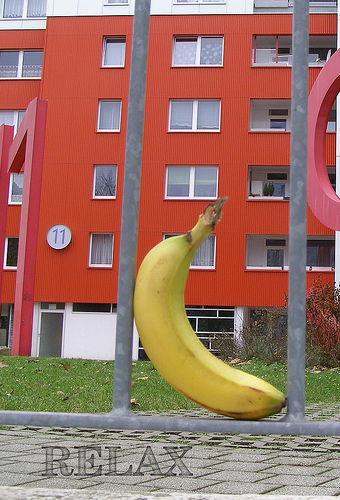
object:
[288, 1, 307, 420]
bar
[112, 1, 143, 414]
bar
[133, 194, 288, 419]
banana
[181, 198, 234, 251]
stem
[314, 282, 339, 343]
leaves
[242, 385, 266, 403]
bruisies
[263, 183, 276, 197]
bush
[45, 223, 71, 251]
circle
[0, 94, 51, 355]
sculpture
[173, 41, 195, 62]
curtain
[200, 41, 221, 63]
curtain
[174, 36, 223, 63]
window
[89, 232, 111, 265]
windows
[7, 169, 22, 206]
window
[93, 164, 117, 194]
window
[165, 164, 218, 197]
window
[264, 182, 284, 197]
window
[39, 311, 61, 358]
glass door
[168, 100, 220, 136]
window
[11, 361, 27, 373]
leaf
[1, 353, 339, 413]
grass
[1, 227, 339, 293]
first floor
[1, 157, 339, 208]
second floor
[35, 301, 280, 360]
bottom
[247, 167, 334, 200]
balcony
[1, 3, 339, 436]
fence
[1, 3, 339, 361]
building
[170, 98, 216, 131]
white curtains